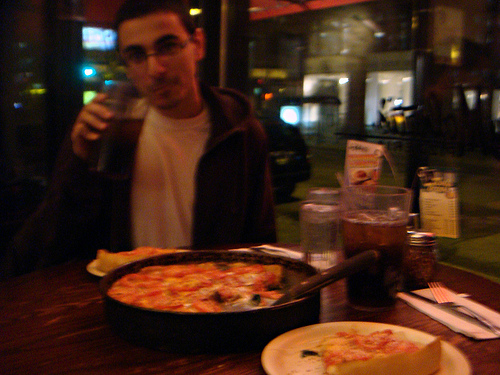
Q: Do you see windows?
A: Yes, there is a window.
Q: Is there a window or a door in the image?
A: Yes, there is a window.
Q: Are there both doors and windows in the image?
A: No, there is a window but no doors.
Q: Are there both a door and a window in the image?
A: No, there is a window but no doors.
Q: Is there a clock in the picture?
A: No, there are no clocks.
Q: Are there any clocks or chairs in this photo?
A: No, there are no clocks or chairs.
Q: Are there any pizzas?
A: Yes, there is a pizza.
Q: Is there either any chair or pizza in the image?
A: Yes, there is a pizza.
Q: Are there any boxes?
A: No, there are no boxes.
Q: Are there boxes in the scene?
A: No, there are no boxes.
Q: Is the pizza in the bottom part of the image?
A: Yes, the pizza is in the bottom of the image.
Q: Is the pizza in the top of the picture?
A: No, the pizza is in the bottom of the image.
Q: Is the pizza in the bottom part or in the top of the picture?
A: The pizza is in the bottom of the image.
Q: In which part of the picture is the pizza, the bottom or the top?
A: The pizza is in the bottom of the image.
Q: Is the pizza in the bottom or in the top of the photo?
A: The pizza is in the bottom of the image.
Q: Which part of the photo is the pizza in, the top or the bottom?
A: The pizza is in the bottom of the image.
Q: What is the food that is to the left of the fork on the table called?
A: The food is a pizza.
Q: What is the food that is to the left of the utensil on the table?
A: The food is a pizza.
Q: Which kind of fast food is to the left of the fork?
A: The food is a pizza.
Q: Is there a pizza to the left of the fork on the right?
A: Yes, there is a pizza to the left of the fork.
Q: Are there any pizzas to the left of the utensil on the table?
A: Yes, there is a pizza to the left of the fork.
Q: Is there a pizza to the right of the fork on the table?
A: No, the pizza is to the left of the fork.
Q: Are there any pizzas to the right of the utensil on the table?
A: No, the pizza is to the left of the fork.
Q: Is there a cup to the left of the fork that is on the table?
A: No, there is a pizza to the left of the fork.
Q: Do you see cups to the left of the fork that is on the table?
A: No, there is a pizza to the left of the fork.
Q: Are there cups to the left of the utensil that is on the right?
A: No, there is a pizza to the left of the fork.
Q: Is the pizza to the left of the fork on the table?
A: Yes, the pizza is to the left of the fork.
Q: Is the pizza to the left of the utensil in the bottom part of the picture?
A: Yes, the pizza is to the left of the fork.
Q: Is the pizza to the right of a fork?
A: No, the pizza is to the left of a fork.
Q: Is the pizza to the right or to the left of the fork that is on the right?
A: The pizza is to the left of the fork.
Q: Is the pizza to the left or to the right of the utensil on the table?
A: The pizza is to the left of the fork.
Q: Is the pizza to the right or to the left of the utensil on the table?
A: The pizza is to the left of the fork.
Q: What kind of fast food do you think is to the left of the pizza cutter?
A: The food is a pizza.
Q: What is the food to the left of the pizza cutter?
A: The food is a pizza.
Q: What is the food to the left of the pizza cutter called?
A: The food is a pizza.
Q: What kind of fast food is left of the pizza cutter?
A: The food is a pizza.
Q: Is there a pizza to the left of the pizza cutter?
A: Yes, there is a pizza to the left of the pizza cutter.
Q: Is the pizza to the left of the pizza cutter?
A: Yes, the pizza is to the left of the pizza cutter.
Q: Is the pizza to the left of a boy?
A: No, the pizza is to the left of the pizza cutter.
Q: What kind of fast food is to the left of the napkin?
A: The food is a pizza.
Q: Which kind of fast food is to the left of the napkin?
A: The food is a pizza.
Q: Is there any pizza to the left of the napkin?
A: Yes, there is a pizza to the left of the napkin.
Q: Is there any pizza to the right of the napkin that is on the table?
A: No, the pizza is to the left of the napkin.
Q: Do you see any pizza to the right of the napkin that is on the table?
A: No, the pizza is to the left of the napkin.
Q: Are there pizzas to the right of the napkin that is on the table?
A: No, the pizza is to the left of the napkin.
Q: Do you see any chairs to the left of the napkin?
A: No, there is a pizza to the left of the napkin.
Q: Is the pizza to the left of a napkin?
A: Yes, the pizza is to the left of a napkin.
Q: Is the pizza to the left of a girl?
A: No, the pizza is to the left of a napkin.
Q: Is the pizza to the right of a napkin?
A: No, the pizza is to the left of a napkin.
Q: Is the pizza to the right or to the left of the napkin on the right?
A: The pizza is to the left of the napkin.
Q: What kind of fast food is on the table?
A: The food is a pizza.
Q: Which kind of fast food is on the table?
A: The food is a pizza.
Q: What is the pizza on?
A: The pizza is on the table.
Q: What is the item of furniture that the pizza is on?
A: The piece of furniture is a table.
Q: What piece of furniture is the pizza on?
A: The pizza is on the table.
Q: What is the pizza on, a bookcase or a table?
A: The pizza is on a table.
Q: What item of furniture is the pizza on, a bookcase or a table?
A: The pizza is on a table.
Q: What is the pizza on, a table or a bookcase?
A: The pizza is on a table.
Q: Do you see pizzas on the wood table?
A: Yes, there is a pizza on the table.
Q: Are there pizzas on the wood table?
A: Yes, there is a pizza on the table.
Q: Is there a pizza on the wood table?
A: Yes, there is a pizza on the table.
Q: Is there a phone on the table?
A: No, there is a pizza on the table.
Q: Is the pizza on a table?
A: Yes, the pizza is on a table.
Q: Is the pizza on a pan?
A: No, the pizza is on a table.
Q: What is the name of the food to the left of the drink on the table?
A: The food is a pizza.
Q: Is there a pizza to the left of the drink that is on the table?
A: Yes, there is a pizza to the left of the drink.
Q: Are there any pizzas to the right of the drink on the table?
A: No, the pizza is to the left of the drink.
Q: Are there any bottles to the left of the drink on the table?
A: No, there is a pizza to the left of the drink.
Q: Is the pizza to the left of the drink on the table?
A: Yes, the pizza is to the left of the drink.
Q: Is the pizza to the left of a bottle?
A: No, the pizza is to the left of the drink.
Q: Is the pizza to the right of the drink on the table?
A: No, the pizza is to the left of the drink.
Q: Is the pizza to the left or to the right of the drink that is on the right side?
A: The pizza is to the left of the drink.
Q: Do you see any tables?
A: Yes, there is a table.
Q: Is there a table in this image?
A: Yes, there is a table.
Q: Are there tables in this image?
A: Yes, there is a table.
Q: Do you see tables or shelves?
A: Yes, there is a table.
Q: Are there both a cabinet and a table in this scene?
A: No, there is a table but no cabinets.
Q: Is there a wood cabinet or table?
A: Yes, there is a wood table.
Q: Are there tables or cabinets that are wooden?
A: Yes, the table is wooden.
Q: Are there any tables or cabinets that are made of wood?
A: Yes, the table is made of wood.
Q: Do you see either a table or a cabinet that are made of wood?
A: Yes, the table is made of wood.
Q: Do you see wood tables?
A: Yes, there is a wood table.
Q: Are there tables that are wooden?
A: Yes, there is a table that is wooden.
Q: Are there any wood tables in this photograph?
A: Yes, there is a table that is made of wood.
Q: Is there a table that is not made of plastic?
A: Yes, there is a table that is made of wood.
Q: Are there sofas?
A: No, there are no sofas.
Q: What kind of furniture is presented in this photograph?
A: The furniture is a table.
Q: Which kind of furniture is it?
A: The piece of furniture is a table.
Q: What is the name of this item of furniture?
A: This is a table.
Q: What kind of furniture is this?
A: This is a table.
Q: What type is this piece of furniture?
A: This is a table.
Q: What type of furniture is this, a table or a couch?
A: This is a table.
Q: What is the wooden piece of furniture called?
A: The piece of furniture is a table.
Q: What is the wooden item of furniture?
A: The piece of furniture is a table.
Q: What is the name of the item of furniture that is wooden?
A: The piece of furniture is a table.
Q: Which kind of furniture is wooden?
A: The furniture is a table.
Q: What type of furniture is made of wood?
A: The furniture is a table.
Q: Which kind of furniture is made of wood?
A: The furniture is a table.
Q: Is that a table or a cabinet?
A: That is a table.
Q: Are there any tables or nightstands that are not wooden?
A: No, there is a table but it is wooden.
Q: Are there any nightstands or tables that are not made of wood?
A: No, there is a table but it is made of wood.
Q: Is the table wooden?
A: Yes, the table is wooden.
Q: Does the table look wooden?
A: Yes, the table is wooden.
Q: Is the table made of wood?
A: Yes, the table is made of wood.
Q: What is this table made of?
A: The table is made of wood.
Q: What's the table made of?
A: The table is made of wood.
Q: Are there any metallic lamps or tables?
A: No, there is a table but it is wooden.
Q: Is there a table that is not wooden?
A: No, there is a table but it is wooden.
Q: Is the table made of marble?
A: No, the table is made of wood.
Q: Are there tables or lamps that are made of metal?
A: No, there is a table but it is made of wood.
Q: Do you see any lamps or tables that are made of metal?
A: No, there is a table but it is made of wood.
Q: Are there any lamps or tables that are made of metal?
A: No, there is a table but it is made of wood.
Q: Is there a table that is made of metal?
A: No, there is a table but it is made of wood.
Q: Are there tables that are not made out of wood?
A: No, there is a table but it is made of wood.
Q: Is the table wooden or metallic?
A: The table is wooden.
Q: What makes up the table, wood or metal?
A: The table is made of wood.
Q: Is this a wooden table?
A: Yes, this is a wooden table.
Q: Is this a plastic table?
A: No, this is a wooden table.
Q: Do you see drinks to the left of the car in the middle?
A: Yes, there is a drink to the left of the car.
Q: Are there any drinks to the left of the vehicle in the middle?
A: Yes, there is a drink to the left of the car.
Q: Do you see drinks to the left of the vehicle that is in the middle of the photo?
A: Yes, there is a drink to the left of the car.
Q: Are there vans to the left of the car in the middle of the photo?
A: No, there is a drink to the left of the car.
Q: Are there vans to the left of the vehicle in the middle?
A: No, there is a drink to the left of the car.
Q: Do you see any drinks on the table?
A: Yes, there is a drink on the table.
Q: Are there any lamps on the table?
A: No, there is a drink on the table.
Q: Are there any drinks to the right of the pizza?
A: Yes, there is a drink to the right of the pizza.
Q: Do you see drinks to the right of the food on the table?
A: Yes, there is a drink to the right of the pizza.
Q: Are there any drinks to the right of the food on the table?
A: Yes, there is a drink to the right of the pizza.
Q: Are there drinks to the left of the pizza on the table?
A: No, the drink is to the right of the pizza.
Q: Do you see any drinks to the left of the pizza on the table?
A: No, the drink is to the right of the pizza.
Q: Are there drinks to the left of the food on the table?
A: No, the drink is to the right of the pizza.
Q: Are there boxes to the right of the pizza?
A: No, there is a drink to the right of the pizza.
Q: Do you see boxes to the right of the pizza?
A: No, there is a drink to the right of the pizza.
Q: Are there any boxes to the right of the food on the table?
A: No, there is a drink to the right of the pizza.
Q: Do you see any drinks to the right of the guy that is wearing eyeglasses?
A: Yes, there is a drink to the right of the guy.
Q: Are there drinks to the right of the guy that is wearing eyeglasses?
A: Yes, there is a drink to the right of the guy.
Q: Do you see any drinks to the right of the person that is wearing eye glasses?
A: Yes, there is a drink to the right of the guy.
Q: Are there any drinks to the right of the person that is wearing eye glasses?
A: Yes, there is a drink to the right of the guy.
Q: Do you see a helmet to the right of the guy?
A: No, there is a drink to the right of the guy.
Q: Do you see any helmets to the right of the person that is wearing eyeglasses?
A: No, there is a drink to the right of the guy.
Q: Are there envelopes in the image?
A: No, there are no envelopes.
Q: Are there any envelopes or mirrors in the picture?
A: No, there are no envelopes or mirrors.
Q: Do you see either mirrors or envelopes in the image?
A: No, there are no envelopes or mirrors.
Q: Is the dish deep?
A: Yes, the dish is deep.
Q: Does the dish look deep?
A: Yes, the dish is deep.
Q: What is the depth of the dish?
A: The dish is deep.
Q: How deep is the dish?
A: The dish is deep.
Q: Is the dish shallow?
A: No, the dish is deep.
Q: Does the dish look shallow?
A: No, the dish is deep.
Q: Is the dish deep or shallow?
A: The dish is deep.